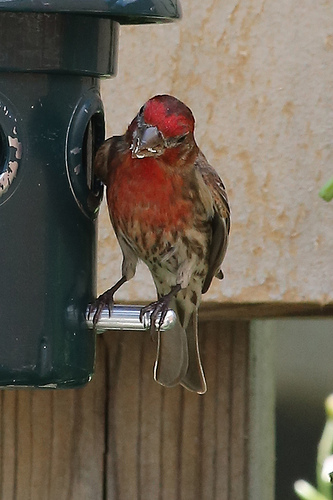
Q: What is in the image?
A: Bird.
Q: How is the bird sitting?
A: On feeder.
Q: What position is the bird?
A: Perched.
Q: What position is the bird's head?
A: Tilted.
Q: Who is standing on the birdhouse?
A: The bird.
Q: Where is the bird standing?
A: On a birdhouse.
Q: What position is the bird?
A: Standing.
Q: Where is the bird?
A: On a birdhouse.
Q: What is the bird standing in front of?
A: Birdhouse.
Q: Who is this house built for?
A: Birds.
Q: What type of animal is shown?
A: Bird.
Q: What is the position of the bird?
A: Standing.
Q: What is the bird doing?
A: Eating.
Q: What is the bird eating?
A: Seeds.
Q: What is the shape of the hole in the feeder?
A: Round.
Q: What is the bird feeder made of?
A: Metal.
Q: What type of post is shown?
A: Wooden.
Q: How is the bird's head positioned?
A: Sideways.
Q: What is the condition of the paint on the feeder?
A: Chipped.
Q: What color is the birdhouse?
A: Green.